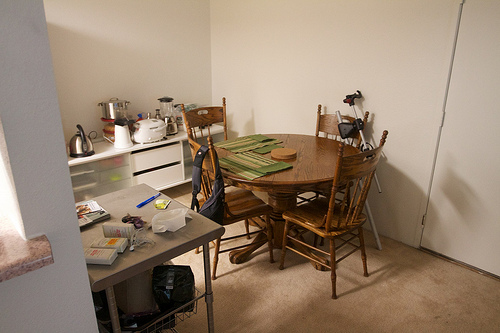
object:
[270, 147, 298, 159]
table decoration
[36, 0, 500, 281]
wall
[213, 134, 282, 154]
placemat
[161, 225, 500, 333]
floor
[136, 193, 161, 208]
blue utencil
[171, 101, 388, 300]
four chairs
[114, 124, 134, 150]
box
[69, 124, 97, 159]
coffee pot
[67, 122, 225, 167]
counter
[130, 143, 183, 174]
drawer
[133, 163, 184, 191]
drawer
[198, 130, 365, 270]
table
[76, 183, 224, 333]
counter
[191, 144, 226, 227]
bag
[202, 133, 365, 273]
brown table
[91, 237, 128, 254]
containers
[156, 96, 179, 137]
metal blender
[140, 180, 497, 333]
carpet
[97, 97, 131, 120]
pan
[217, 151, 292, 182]
books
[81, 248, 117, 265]
box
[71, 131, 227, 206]
cabinet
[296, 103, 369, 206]
chair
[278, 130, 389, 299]
chair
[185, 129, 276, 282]
chair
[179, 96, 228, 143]
chair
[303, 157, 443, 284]
shadow